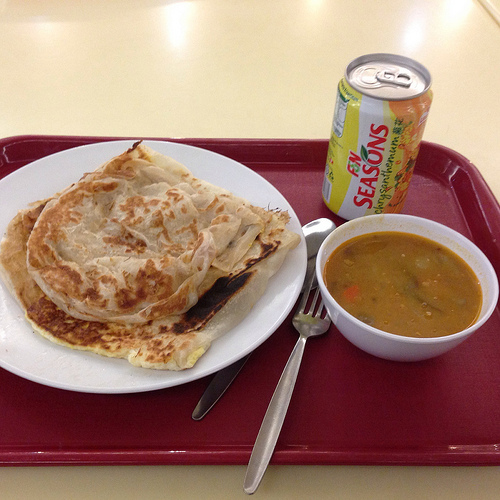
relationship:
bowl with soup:
[305, 205, 490, 372] [356, 250, 439, 319]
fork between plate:
[253, 287, 318, 479] [13, 146, 271, 395]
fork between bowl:
[253, 287, 318, 479] [320, 210, 484, 352]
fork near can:
[190, 215, 338, 421] [316, 60, 427, 222]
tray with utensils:
[448, 136, 498, 203] [193, 187, 341, 478]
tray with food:
[448, 136, 498, 203] [23, 169, 224, 293]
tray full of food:
[0, 134, 497, 469] [0, 51, 485, 373]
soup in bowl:
[322, 231, 479, 338] [312, 213, 497, 357]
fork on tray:
[240, 265, 333, 497] [0, 134, 497, 469]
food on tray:
[3, 141, 488, 368] [0, 134, 497, 469]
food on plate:
[0, 51, 485, 373] [0, 139, 309, 396]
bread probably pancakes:
[0, 142, 303, 371] [57, 160, 210, 306]